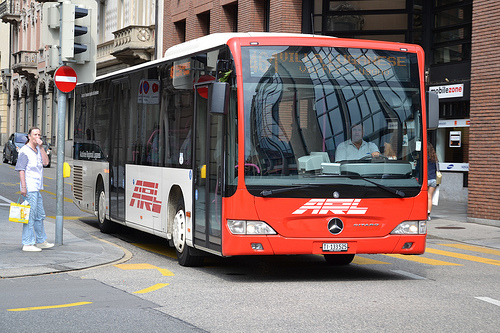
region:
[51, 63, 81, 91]
a red and white street sign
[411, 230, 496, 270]
a yellow street marking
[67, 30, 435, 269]
a large red and white bus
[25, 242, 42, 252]
a white tennis shoe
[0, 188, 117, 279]
part of a sidewalk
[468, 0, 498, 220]
part of a brick building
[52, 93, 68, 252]
a long gray pole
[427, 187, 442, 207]
a white bag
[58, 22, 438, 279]
A red public transportation bus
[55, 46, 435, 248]
red and white bus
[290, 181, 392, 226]
white logo on bus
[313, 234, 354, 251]
black and white license plate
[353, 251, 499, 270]
yellow lines on road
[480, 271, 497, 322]
white lines on road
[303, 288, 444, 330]
road is dark grey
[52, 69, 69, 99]
red and white sign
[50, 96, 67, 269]
sign on grey pole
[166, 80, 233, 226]
black door on bus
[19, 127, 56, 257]
person standing on curb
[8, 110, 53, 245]
a woman at the sidewalk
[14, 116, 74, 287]
a woman at the sidewalk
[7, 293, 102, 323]
the line is yellow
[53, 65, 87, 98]
prohibited sign on the post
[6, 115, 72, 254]
person standing on the street corner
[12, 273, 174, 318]
yellow lines on the pavement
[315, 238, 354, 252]
license plate on the bus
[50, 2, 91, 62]
traffic light on the pole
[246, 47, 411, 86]
led screen on the front of the bus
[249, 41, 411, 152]
reflection in the large window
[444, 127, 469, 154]
atm in the building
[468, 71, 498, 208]
red brick wall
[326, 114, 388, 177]
bus driver is wearing a white shirt